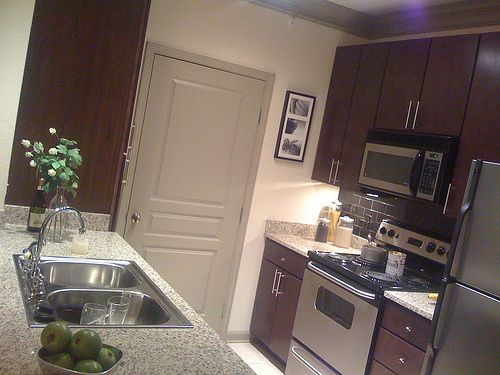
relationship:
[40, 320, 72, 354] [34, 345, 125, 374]
apple in bowl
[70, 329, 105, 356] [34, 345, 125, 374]
apple in bowl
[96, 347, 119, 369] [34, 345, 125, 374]
apple in bowl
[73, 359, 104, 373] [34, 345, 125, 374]
apple in bowl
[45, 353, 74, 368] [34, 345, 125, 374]
apple in bowl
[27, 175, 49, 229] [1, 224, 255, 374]
bottle on counter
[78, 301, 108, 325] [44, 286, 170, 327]
glass in sink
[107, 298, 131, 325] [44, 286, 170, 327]
glass in sink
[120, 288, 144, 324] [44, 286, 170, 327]
glass in sink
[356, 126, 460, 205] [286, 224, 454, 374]
microwave above stove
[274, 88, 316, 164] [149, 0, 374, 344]
picture on wall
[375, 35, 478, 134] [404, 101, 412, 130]
cupboard has handle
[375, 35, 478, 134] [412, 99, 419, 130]
cupboard has handle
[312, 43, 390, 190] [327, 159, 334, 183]
cupboard has handle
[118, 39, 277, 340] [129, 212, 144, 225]
door has knob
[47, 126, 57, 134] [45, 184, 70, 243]
flower in vase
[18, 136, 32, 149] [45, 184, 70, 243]
flower in vase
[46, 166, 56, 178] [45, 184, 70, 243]
flower in vase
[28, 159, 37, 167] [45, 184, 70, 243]
flower in vase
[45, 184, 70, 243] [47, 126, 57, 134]
vase with rose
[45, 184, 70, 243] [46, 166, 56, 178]
vase with rose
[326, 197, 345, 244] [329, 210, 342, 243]
jar of pasta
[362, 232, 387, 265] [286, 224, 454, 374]
pot on stove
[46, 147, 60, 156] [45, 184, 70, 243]
flower in vase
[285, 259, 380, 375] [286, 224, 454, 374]
face of stove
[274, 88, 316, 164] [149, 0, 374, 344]
photo on wall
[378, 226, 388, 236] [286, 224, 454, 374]
dial on stove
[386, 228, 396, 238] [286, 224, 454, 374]
dial on stove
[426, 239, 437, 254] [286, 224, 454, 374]
dial on stove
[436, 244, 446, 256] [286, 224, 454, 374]
dial on stove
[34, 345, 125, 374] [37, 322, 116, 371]
bowl of apples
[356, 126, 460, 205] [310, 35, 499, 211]
microwave in cabinets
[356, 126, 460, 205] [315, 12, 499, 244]
microwave on wall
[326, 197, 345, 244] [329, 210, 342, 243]
jar of food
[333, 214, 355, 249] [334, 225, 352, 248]
jar of food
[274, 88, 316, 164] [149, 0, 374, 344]
artwork on wall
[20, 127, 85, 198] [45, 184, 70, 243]
plant in vase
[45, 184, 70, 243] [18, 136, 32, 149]
vase with flower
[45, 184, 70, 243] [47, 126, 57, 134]
vase with flower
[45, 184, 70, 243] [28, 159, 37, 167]
vase with flower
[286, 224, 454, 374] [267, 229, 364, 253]
oven by counter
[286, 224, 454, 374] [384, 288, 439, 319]
oven by counter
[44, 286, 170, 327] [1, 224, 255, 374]
sink on counter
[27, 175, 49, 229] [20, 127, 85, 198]
bottle by flowers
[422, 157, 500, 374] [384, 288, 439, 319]
fridge by counter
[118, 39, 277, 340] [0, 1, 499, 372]
door for kitchen